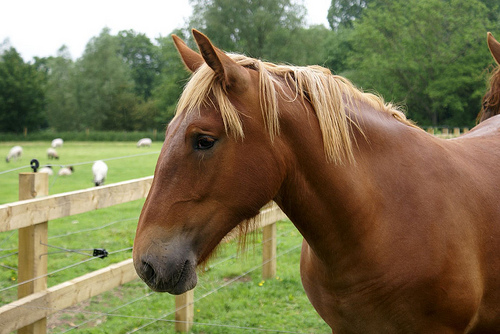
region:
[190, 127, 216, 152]
eye of a horse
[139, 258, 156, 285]
a horse's nostril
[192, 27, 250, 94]
a brown horse's ear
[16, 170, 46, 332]
wooden post on a fence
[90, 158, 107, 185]
a sheep in a field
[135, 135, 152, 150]
a sheep in a field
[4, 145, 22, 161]
a sheep in a field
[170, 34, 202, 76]
ear of a horse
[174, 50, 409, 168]
a horse's mane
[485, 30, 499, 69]
ear of a horse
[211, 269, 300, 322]
Bright green field grass.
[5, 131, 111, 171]
Sheep grazing in the field.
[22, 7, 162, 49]
Patch of bright sky.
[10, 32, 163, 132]
Green trees in the distance.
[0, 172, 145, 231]
Wooden fence to keep the horse safe.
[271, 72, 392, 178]
Long tan mane of the horse.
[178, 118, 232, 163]
Eye of a brown horse.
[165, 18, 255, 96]
Ears of a brown horse.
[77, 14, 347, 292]
Large head of a horse.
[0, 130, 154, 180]
Seven sheep in the field.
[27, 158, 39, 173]
Black sheep in the field.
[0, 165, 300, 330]
Wood fence behind the horse.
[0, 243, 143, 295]
Wire along the wood fence.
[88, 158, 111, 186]
White sheep eating the grass.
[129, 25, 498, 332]
Brown horse in the forefront.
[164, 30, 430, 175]
Cream colored mane on horse.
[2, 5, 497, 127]
Trees in the background.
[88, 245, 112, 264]
Black clip on wire.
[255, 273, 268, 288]
Dandelions in the grass.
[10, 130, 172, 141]
Green hedge in the background.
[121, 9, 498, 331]
a horse by a fence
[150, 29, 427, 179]
the mane is blonde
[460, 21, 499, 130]
another horse behind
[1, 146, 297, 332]
the fence is wooden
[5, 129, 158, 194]
sheep on the other side of the fence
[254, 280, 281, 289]
dandelions on the ground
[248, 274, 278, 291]
the dandelions are yellow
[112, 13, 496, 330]
the horse is brown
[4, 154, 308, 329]
wire in the fence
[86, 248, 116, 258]
a black clip in the wires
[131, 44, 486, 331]
this is a horse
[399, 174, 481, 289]
the horse is brown in color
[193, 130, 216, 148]
this is the eye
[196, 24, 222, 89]
this is the ear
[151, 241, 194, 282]
the mouth is closed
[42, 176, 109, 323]
this is a fence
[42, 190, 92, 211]
the fence is wooden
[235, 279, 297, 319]
the grass are green in color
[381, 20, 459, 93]
the trees are leafy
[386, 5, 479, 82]
the leaves are green in color